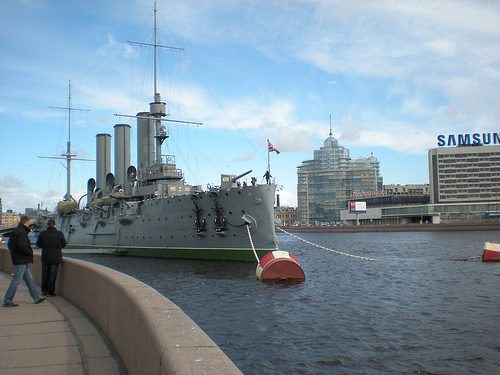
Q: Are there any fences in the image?
A: No, there are no fences.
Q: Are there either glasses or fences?
A: No, there are no fences or glasses.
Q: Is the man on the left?
A: Yes, the man is on the left of the image.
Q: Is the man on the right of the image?
A: No, the man is on the left of the image.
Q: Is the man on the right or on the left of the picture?
A: The man is on the left of the image.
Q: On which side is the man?
A: The man is on the left of the image.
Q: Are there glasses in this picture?
A: No, there are no glasses.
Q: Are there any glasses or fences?
A: No, there are no glasses or fences.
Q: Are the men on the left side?
A: Yes, the men are on the left of the image.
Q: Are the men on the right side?
A: No, the men are on the left of the image.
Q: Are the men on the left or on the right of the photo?
A: The men are on the left of the image.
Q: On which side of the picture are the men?
A: The men are on the left of the image.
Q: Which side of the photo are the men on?
A: The men are on the left of the image.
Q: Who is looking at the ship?
A: The men are looking at the ship.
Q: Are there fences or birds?
A: No, there are no fences or birds.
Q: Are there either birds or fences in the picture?
A: No, there are no fences or birds.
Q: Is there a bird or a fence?
A: No, there are no fences or birds.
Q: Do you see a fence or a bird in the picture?
A: No, there are no fences or birds.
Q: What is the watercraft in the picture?
A: The watercraft is a ship.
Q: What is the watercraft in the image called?
A: The watercraft is a ship.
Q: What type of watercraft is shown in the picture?
A: The watercraft is a ship.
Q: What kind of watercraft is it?
A: The watercraft is a ship.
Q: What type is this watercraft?
A: That is a ship.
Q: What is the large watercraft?
A: The watercraft is a ship.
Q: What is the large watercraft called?
A: The watercraft is a ship.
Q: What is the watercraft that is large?
A: The watercraft is a ship.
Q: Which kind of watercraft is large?
A: The watercraft is a ship.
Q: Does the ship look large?
A: Yes, the ship is large.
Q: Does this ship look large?
A: Yes, the ship is large.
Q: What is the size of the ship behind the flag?
A: The ship is large.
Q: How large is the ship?
A: The ship is large.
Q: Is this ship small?
A: No, the ship is large.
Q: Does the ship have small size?
A: No, the ship is large.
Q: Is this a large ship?
A: Yes, this is a large ship.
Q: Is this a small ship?
A: No, this is a large ship.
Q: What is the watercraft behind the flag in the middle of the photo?
A: The watercraft is a ship.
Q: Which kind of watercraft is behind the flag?
A: The watercraft is a ship.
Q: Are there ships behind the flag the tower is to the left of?
A: Yes, there is a ship behind the flag.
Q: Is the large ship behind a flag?
A: Yes, the ship is behind a flag.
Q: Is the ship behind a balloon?
A: No, the ship is behind a flag.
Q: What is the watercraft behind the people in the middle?
A: The watercraft is a ship.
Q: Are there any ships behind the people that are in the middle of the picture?
A: Yes, there is a ship behind the people.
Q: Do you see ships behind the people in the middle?
A: Yes, there is a ship behind the people.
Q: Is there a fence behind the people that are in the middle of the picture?
A: No, there is a ship behind the people.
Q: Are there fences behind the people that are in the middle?
A: No, there is a ship behind the people.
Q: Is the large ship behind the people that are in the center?
A: Yes, the ship is behind the people.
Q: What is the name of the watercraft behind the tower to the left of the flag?
A: The watercraft is a ship.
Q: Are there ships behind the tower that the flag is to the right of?
A: Yes, there is a ship behind the tower.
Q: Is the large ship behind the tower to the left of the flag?
A: Yes, the ship is behind the tower.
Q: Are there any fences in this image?
A: No, there are no fences.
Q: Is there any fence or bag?
A: No, there are no fences or bags.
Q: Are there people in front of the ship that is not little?
A: Yes, there are people in front of the ship.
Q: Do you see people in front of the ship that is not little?
A: Yes, there are people in front of the ship.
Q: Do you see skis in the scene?
A: No, there are no skis.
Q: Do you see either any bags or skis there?
A: No, there are no skis or bags.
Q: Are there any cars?
A: No, there are no cars.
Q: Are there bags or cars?
A: No, there are no cars or bags.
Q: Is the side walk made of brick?
A: Yes, the side walk is made of brick.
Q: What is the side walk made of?
A: The side walk is made of brick.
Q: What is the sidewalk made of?
A: The side walk is made of brick.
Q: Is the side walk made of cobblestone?
A: No, the side walk is made of brick.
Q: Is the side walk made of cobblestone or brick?
A: The side walk is made of brick.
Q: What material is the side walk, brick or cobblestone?
A: The side walk is made of brick.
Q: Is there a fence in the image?
A: No, there are no fences.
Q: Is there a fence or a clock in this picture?
A: No, there are no fences or clocks.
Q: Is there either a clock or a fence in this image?
A: No, there are no fences or clocks.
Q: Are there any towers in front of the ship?
A: Yes, there is a tower in front of the ship.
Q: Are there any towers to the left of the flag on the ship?
A: Yes, there is a tower to the left of the flag.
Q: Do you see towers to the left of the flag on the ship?
A: Yes, there is a tower to the left of the flag.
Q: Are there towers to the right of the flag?
A: No, the tower is to the left of the flag.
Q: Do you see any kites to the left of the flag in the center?
A: No, there is a tower to the left of the flag.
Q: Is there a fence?
A: No, there are no fences.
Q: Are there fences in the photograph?
A: No, there are no fences.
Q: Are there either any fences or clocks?
A: No, there are no fences or clocks.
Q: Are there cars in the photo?
A: No, there are no cars.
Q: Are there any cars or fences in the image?
A: No, there are no cars or fences.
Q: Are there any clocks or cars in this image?
A: No, there are no cars or clocks.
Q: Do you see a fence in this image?
A: No, there are no fences.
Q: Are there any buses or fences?
A: No, there are no fences or buses.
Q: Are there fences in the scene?
A: No, there are no fences.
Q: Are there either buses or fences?
A: No, there are no fences or buses.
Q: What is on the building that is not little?
A: The sign is on the building.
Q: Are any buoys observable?
A: Yes, there is a buoy.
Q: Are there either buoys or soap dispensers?
A: Yes, there is a buoy.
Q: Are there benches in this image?
A: No, there are no benches.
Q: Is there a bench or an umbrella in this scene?
A: No, there are no benches or umbrellas.